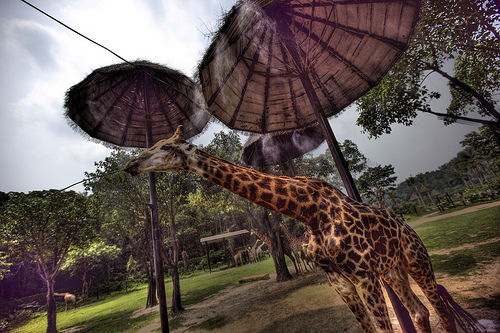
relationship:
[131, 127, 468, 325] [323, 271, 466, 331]
giraffe has legs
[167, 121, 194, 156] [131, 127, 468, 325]
horns are in giraffe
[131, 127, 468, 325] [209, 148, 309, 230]
giraffe has neck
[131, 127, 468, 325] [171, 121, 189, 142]
giraffe has horn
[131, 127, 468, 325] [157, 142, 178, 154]
giraffe has eye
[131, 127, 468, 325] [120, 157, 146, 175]
giraffe has mouth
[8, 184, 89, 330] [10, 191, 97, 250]
tree has leaves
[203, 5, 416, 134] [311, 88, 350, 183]
umbrella has pole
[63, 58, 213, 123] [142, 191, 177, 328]
umbrella has pole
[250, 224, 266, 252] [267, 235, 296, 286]
giraffe behind bark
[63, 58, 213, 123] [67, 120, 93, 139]
umbrella has frills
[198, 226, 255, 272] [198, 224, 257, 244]
structure has roof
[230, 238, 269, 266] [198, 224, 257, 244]
giraffes under roof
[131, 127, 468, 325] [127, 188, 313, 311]
animals near building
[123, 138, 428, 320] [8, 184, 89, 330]
animals clustered by tree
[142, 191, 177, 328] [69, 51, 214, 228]
pole attached to umbrella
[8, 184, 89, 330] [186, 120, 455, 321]
trees behind giraffe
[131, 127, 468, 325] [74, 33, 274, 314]
giraffe under umbrella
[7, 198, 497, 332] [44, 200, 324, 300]
ground on grass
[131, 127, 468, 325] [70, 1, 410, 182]
giraffe under umbrellas